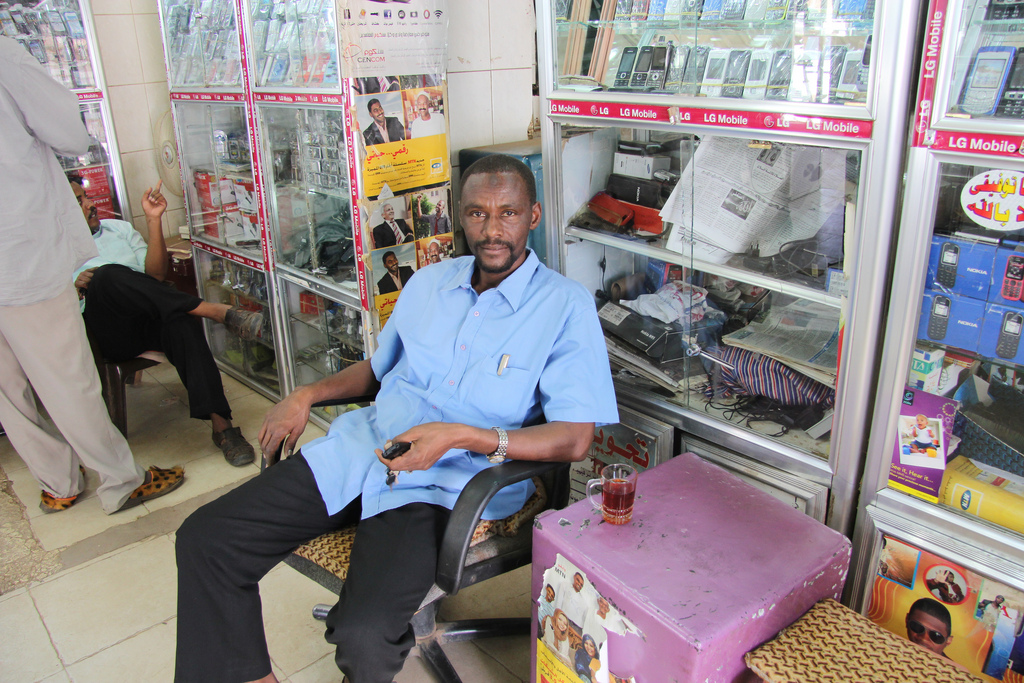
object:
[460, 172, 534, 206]
forehead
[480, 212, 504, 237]
nose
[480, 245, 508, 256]
mouth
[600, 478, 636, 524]
beverage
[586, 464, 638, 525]
glass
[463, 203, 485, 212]
eyebrows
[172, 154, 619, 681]
man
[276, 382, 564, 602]
chair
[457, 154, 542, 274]
head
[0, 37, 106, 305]
shirt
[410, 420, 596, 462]
wrist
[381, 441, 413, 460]
cell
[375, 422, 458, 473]
hand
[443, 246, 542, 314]
collar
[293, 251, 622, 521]
shirt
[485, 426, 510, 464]
watch